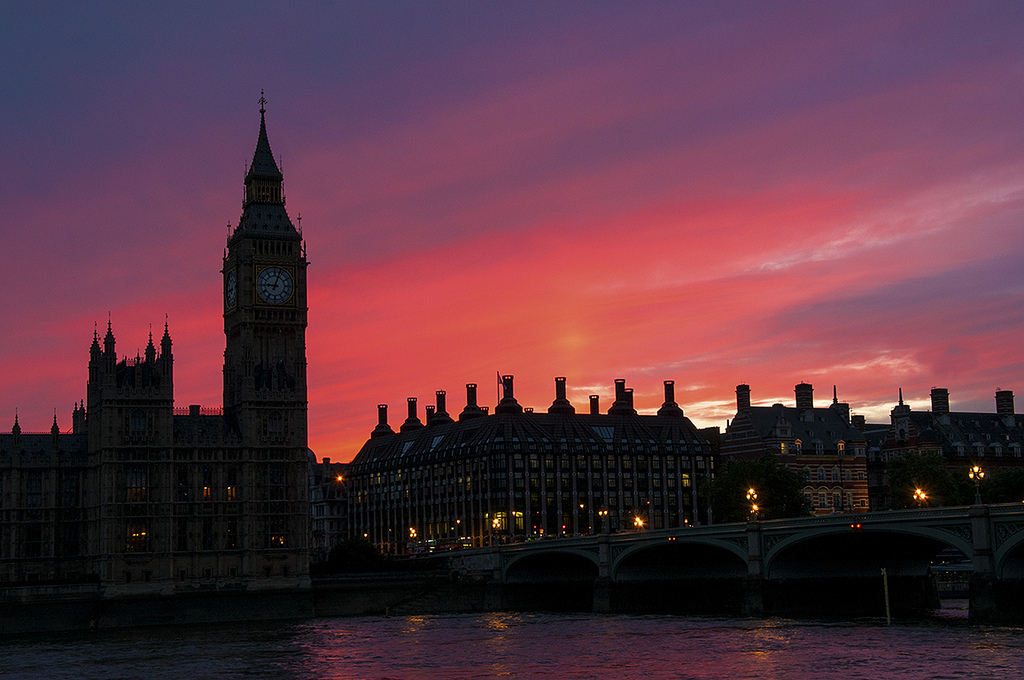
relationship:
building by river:
[217, 89, 312, 461] [155, 592, 922, 675]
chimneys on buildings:
[391, 337, 966, 435] [336, 374, 896, 658]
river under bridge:
[1, 604, 1023, 678] [318, 492, 1023, 631]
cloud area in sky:
[0, 0, 1024, 464] [5, 3, 1021, 470]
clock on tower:
[252, 264, 299, 304] [212, 81, 331, 600]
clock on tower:
[255, 265, 301, 311] [212, 81, 331, 600]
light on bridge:
[736, 474, 782, 523] [413, 492, 1011, 620]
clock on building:
[252, 264, 299, 304] [212, 87, 322, 605]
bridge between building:
[340, 498, 1024, 620] [337, 377, 1007, 528]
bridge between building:
[340, 498, 1024, 620] [6, 81, 324, 633]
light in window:
[126, 514, 161, 552] [108, 507, 172, 565]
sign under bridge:
[934, 589, 983, 629] [340, 498, 1024, 620]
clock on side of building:
[221, 262, 300, 317] [219, 74, 326, 505]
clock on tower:
[252, 264, 299, 304] [219, 87, 317, 479]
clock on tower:
[221, 262, 300, 317] [219, 87, 317, 479]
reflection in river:
[288, 611, 1024, 680] [18, 597, 1021, 673]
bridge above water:
[340, 497, 1023, 591] [7, 595, 1004, 663]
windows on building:
[373, 439, 669, 507] [327, 366, 732, 531]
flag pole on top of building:
[489, 370, 526, 420] [340, 368, 712, 533]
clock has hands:
[221, 262, 300, 317] [269, 279, 295, 299]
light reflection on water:
[403, 608, 434, 637] [293, 621, 1019, 669]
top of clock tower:
[252, 83, 278, 142] [224, 87, 311, 470]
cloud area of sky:
[0, 0, 1024, 464] [5, 3, 1021, 470]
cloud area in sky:
[3, 3, 222, 151] [5, 3, 1021, 470]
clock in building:
[252, 264, 299, 304] [217, 89, 312, 461]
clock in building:
[221, 262, 300, 317] [217, 89, 312, 461]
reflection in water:
[372, 627, 742, 671] [25, 616, 1009, 666]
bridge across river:
[340, 498, 1024, 620] [18, 597, 1021, 673]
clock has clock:
[221, 262, 300, 317] [252, 264, 299, 304]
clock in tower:
[221, 262, 300, 317] [225, 85, 314, 611]